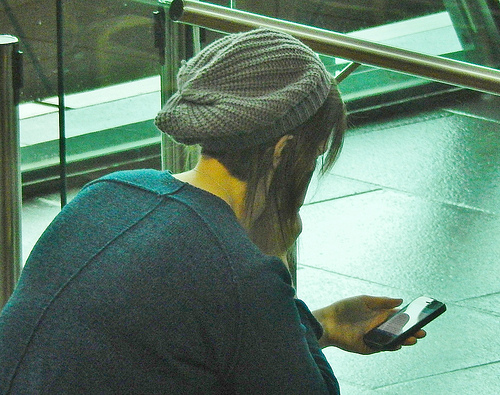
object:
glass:
[106, 25, 141, 104]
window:
[1, 0, 165, 202]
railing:
[170, 0, 499, 96]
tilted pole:
[332, 62, 365, 89]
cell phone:
[358, 294, 446, 350]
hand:
[249, 193, 302, 257]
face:
[291, 124, 335, 213]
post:
[0, 33, 25, 310]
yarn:
[180, 58, 188, 67]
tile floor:
[16, 91, 498, 394]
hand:
[326, 292, 429, 358]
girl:
[0, 26, 430, 394]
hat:
[154, 26, 337, 153]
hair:
[213, 78, 349, 259]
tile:
[372, 359, 500, 394]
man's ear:
[270, 134, 293, 173]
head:
[199, 26, 352, 225]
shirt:
[0, 167, 343, 394]